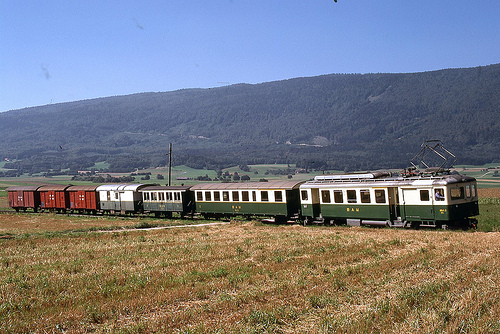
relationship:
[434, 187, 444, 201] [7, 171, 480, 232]
man driving train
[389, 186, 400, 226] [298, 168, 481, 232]
entrance to train car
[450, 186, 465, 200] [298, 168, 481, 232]
window of train car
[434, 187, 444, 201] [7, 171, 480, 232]
man in train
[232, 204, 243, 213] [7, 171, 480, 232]
sign on train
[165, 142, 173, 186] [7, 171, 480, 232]
pole by train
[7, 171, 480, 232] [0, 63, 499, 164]
train by hill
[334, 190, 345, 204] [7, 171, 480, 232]
window on train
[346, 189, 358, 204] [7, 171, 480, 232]
window on train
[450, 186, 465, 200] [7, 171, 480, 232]
window on train